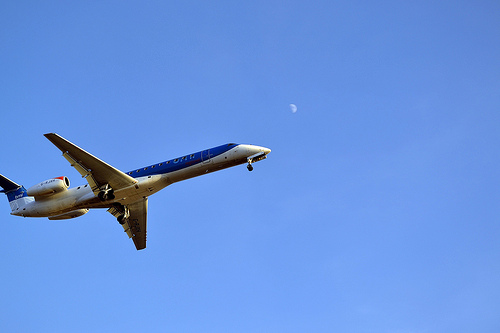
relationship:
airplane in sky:
[0, 132, 272, 251] [0, 1, 499, 333]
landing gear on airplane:
[97, 183, 132, 226] [0, 132, 272, 251]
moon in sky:
[289, 102, 299, 116] [0, 1, 499, 333]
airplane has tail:
[0, 132, 272, 251] [0, 174, 33, 221]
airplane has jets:
[0, 132, 272, 251] [25, 175, 90, 222]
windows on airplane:
[127, 152, 197, 177] [0, 132, 272, 251]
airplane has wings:
[0, 132, 272, 251] [43, 130, 148, 250]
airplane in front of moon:
[0, 132, 272, 251] [289, 102, 299, 116]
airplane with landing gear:
[0, 132, 272, 251] [97, 183, 132, 226]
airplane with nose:
[0, 132, 272, 251] [237, 140, 272, 158]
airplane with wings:
[0, 132, 272, 251] [43, 130, 148, 250]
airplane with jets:
[0, 132, 272, 251] [25, 175, 90, 222]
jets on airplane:
[25, 175, 90, 222] [0, 132, 272, 251]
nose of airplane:
[237, 140, 272, 158] [0, 132, 272, 251]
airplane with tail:
[0, 132, 272, 251] [0, 174, 33, 221]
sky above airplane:
[0, 1, 499, 333] [0, 132, 272, 251]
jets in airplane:
[25, 175, 90, 222] [0, 132, 272, 251]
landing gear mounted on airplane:
[244, 158, 254, 172] [0, 132, 272, 251]